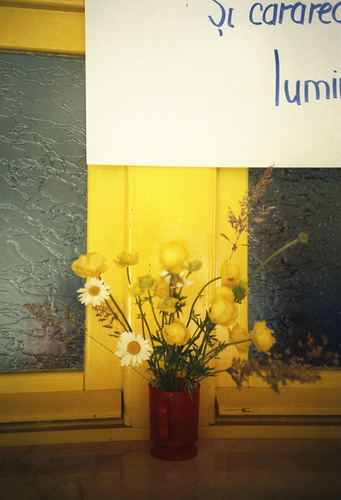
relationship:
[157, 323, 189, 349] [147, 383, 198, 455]
flower in vase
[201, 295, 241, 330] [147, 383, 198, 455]
flower in vase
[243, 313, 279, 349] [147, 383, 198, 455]
flower in vase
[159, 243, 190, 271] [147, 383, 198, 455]
flower in vase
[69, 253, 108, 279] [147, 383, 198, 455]
flower in vase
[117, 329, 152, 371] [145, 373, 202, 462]
flower in cup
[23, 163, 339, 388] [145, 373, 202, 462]
brush in cup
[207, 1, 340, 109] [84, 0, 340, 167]
writing on paper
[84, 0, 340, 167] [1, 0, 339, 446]
paper on wall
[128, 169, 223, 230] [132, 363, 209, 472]
wall behind vase